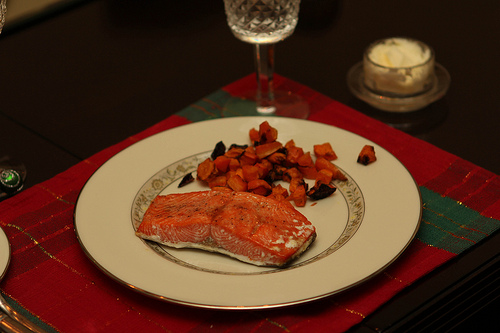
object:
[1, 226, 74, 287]
stripe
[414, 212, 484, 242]
green stripe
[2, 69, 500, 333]
placemat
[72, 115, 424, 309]
plate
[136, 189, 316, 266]
salmon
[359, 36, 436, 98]
butter dish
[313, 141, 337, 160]
orange vegetable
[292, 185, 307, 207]
orange vegetable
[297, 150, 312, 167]
orange vegetable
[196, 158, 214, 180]
orange vegetable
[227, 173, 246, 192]
orange vegetable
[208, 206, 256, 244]
flowers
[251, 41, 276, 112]
stem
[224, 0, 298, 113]
glass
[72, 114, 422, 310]
rim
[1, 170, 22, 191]
mark